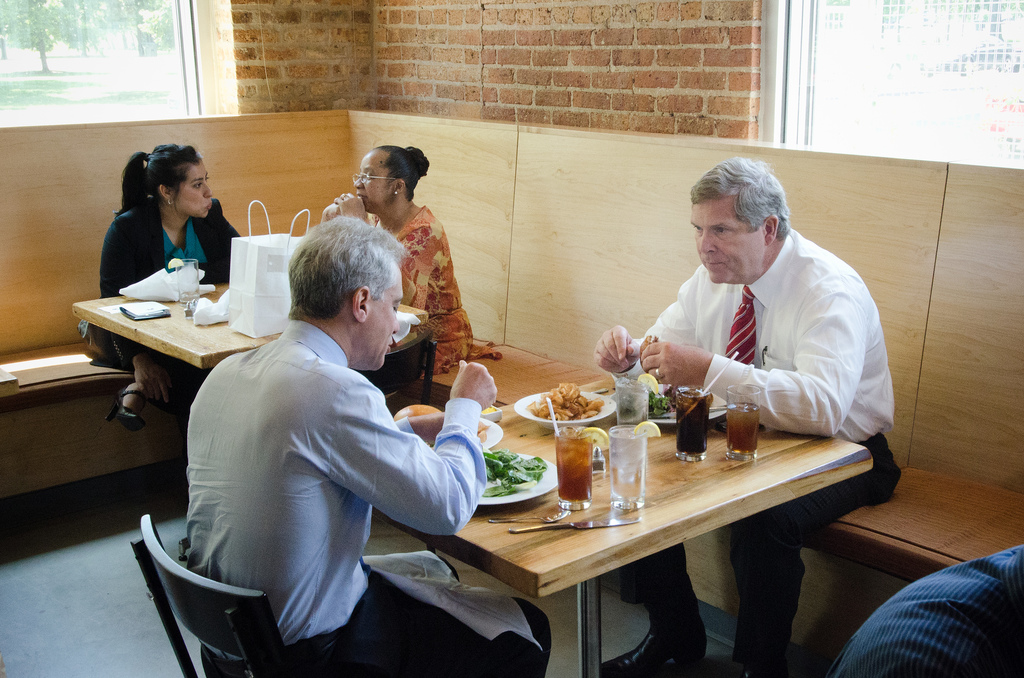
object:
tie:
[728, 284, 765, 365]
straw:
[554, 426, 595, 512]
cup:
[554, 426, 595, 512]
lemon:
[583, 420, 662, 451]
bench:
[356, 110, 1024, 574]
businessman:
[592, 156, 907, 571]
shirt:
[721, 285, 761, 364]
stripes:
[727, 284, 756, 361]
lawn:
[28, 68, 102, 107]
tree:
[6, 10, 55, 72]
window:
[0, 29, 237, 126]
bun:
[406, 146, 429, 176]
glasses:
[352, 172, 393, 183]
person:
[324, 130, 471, 373]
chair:
[131, 513, 284, 660]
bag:
[229, 199, 310, 339]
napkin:
[358, 550, 544, 650]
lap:
[360, 597, 552, 663]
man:
[598, 155, 898, 443]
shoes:
[594, 634, 723, 674]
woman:
[97, 146, 240, 301]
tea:
[554, 428, 590, 502]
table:
[348, 371, 873, 598]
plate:
[477, 448, 550, 498]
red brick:
[613, 86, 676, 108]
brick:
[239, 22, 376, 105]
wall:
[240, 3, 748, 109]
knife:
[499, 517, 641, 534]